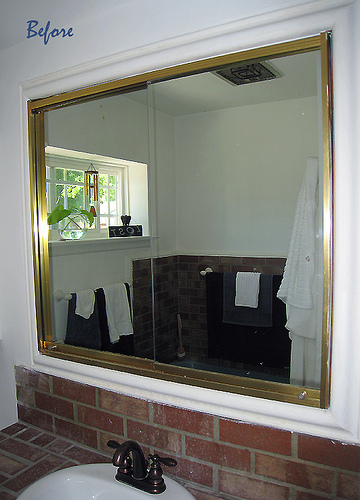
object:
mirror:
[27, 29, 332, 411]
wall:
[0, 0, 360, 448]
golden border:
[27, 31, 330, 409]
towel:
[235, 271, 262, 308]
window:
[44, 142, 151, 244]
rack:
[54, 278, 132, 301]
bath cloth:
[276, 175, 317, 309]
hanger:
[307, 157, 318, 184]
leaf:
[48, 205, 73, 225]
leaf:
[80, 210, 94, 227]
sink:
[15, 462, 197, 500]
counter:
[0, 365, 360, 500]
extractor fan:
[211, 61, 286, 88]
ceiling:
[0, 0, 313, 86]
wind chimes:
[85, 163, 98, 203]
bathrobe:
[284, 177, 319, 387]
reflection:
[177, 314, 185, 360]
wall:
[132, 255, 292, 378]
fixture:
[107, 440, 178, 494]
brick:
[53, 377, 96, 407]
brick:
[77, 404, 124, 436]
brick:
[219, 419, 291, 456]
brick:
[185, 435, 251, 472]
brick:
[298, 433, 360, 473]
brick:
[35, 391, 74, 421]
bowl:
[58, 215, 88, 240]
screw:
[298, 390, 308, 400]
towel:
[94, 283, 134, 344]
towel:
[70, 288, 95, 319]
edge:
[48, 236, 160, 257]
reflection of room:
[43, 48, 324, 392]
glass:
[43, 48, 323, 390]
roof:
[0, 0, 121, 49]